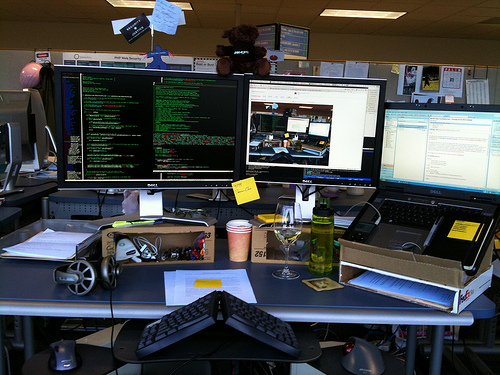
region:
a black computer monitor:
[51, 65, 245, 229]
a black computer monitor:
[240, 72, 383, 223]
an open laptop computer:
[341, 102, 498, 276]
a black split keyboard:
[135, 289, 297, 356]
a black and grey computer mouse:
[48, 336, 81, 372]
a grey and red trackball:
[336, 334, 386, 373]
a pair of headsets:
[49, 255, 122, 295]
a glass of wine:
[270, 198, 305, 283]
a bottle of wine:
[311, 195, 335, 274]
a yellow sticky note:
[228, 177, 261, 204]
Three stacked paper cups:
[225, 218, 252, 263]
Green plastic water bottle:
[309, 198, 334, 275]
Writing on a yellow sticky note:
[230, 174, 260, 206]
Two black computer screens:
[52, 58, 389, 199]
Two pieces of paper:
[161, 265, 256, 311]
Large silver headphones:
[50, 253, 125, 296]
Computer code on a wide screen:
[62, 70, 238, 180]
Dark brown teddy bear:
[213, 21, 272, 78]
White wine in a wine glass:
[270, 200, 304, 280]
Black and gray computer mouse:
[46, 337, 84, 374]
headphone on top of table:
[47, 253, 125, 294]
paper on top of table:
[145, 256, 263, 310]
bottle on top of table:
[296, 196, 354, 291]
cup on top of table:
[223, 209, 270, 271]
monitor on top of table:
[53, 66, 248, 203]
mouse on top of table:
[47, 332, 91, 367]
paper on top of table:
[3, 202, 104, 276]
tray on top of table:
[2, 218, 109, 265]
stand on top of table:
[96, 213, 226, 271]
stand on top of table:
[243, 215, 361, 269]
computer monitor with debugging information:
[54, 65, 246, 185]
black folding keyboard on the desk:
[137, 289, 301, 356]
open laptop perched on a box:
[343, 107, 498, 276]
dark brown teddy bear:
[215, 23, 270, 76]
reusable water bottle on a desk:
[305, 196, 335, 271]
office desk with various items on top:
[0, 215, 495, 320]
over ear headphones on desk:
[52, 254, 125, 301]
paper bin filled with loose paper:
[0, 218, 105, 266]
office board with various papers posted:
[0, 48, 499, 105]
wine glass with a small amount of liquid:
[271, 193, 307, 281]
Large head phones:
[50, 249, 134, 295]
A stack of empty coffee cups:
[225, 218, 257, 263]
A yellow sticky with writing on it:
[227, 171, 263, 207]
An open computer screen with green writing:
[46, 58, 258, 190]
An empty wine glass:
[271, 198, 307, 284]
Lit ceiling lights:
[314, 4, 409, 26]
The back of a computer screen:
[0, 85, 42, 207]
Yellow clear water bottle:
[303, 200, 339, 278]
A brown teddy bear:
[212, 22, 278, 79]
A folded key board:
[139, 287, 301, 363]